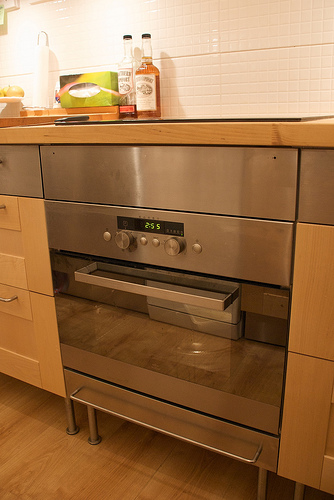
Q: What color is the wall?
A: White.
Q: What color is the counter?
A: Brown.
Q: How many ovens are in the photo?
A: One.